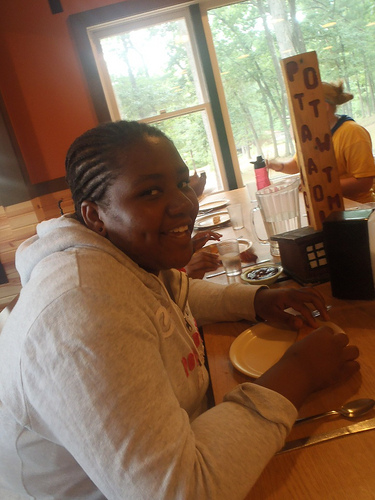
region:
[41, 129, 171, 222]
girl has dark hair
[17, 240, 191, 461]
girl has white hoodie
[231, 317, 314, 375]
girl has hands on plate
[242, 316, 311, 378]
circular plate is white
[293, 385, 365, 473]
silverware is on table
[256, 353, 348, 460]
table is brown and wooden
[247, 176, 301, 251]
clear pitcher on table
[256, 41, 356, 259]
sign is white and red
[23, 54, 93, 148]
wall is dark orange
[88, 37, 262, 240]
white frame around window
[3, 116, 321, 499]
that is a person in the picture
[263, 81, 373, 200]
that is a person in the picture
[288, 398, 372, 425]
that is a spoon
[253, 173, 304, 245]
that is a jug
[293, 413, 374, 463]
that is a table knife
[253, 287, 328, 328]
that is a hand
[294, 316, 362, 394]
that is a hand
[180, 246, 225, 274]
that is a hand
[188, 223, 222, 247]
that is a hand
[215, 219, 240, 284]
that is a glass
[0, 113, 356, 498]
person is smiling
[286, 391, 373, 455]
spoon and fork on side of man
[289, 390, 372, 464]
spoon and knife on table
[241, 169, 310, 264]
jar of water on table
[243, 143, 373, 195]
a person wearing yellow tee shirt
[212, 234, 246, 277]
a glass of water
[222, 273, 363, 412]
two hands on a white dish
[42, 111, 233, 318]
person is smiling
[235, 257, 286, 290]
a bowl of sauce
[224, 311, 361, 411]
white dish is empty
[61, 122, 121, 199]
the corn rows in the hair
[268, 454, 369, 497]
the top of the wooden table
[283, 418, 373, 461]
the silver butter knife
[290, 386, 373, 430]
the silver spoon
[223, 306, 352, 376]
the white round plate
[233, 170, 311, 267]
the clear water pitcher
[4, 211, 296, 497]
the long sleeved gray sweat shirt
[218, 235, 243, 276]
the clear cup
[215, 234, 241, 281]
the clear cup of water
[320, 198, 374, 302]
the napkin dispenser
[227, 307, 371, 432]
the plate is white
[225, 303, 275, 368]
the plate is white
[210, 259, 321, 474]
the plate is white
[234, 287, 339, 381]
the plate is white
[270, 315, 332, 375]
the plate is white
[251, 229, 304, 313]
the plate is white